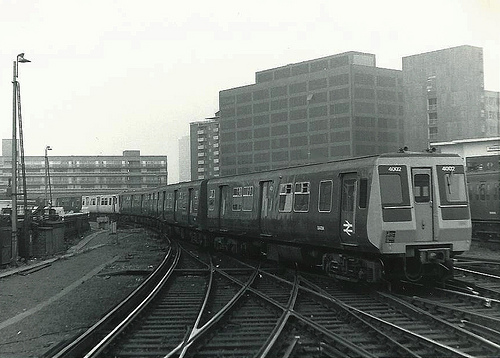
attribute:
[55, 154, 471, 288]
train — long, running, light colored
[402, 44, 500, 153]
building — tall, big, wide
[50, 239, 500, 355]
train tracks — criss crossed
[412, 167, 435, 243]
door — metal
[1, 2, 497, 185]
sky — gray, white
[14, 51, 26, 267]
pole — grey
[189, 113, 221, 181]
building — small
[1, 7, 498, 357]
picture — black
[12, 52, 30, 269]
steet light — tall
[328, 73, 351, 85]
window — rectangular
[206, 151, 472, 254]
car — light, older